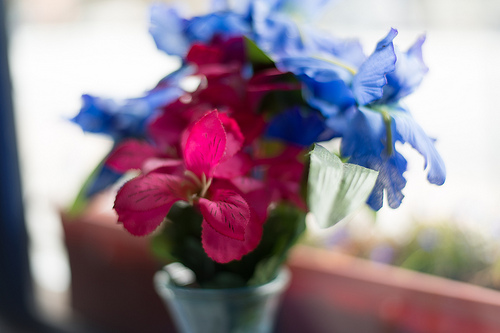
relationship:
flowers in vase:
[58, 3, 461, 274] [149, 263, 297, 331]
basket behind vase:
[61, 184, 497, 332] [149, 263, 297, 331]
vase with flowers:
[149, 263, 297, 331] [58, 3, 461, 274]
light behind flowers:
[21, 9, 496, 246] [58, 3, 461, 274]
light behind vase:
[21, 9, 496, 246] [149, 263, 297, 331]